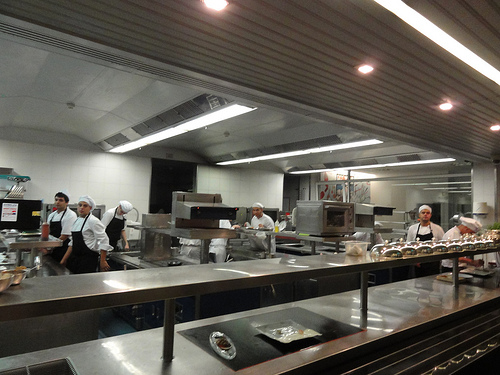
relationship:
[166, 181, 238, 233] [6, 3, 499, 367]
warmer in kitchen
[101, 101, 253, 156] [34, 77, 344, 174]
lights on ceiling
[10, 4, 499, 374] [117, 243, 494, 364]
cafeteria has shelf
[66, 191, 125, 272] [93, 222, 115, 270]
cooker has left arm